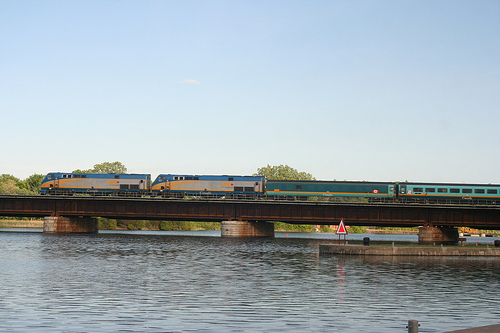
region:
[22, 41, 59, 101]
the sky is clear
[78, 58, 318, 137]
the sky is clear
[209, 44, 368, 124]
the sky is clear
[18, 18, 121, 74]
the sky is clear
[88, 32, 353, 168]
the sky is clear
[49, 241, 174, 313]
the water is calm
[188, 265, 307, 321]
the water is calm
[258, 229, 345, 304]
the water is calm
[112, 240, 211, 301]
the water is calm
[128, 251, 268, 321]
the water is calm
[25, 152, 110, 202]
blue train in the front with yellow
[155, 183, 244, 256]
second train with yellow body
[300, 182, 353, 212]
third train is green and short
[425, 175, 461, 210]
fourth train has windows on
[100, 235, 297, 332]
calm river with no ducks in it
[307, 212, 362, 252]
a random sign in middle of river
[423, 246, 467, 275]
some sort of island in middle of water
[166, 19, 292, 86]
bright blue sky with no cloud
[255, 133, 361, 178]
a random tree behind trains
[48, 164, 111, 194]
a train pilot eating a sandwich in front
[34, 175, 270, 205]
yellow and black train engines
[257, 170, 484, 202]
green train cars on bridge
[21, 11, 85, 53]
white clouds in blue sky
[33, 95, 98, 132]
white clouds in blue sky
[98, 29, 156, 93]
white clouds in blue sky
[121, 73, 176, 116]
white clouds in blue sky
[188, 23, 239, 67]
white clouds in blue sky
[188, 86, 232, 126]
white clouds in blue sky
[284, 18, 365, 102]
white clouds in blue sky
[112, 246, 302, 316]
This is a large river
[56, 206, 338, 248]
These are stumps of brick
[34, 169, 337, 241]
This is a train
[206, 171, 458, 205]
These are train cars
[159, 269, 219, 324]
The lake is brown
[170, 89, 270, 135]
There are no clouds in the sky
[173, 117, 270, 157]
There are no planes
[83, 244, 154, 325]
There are no people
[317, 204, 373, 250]
This is a triangular sign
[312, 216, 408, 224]
The sign is red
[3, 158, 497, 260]
train riding along bridge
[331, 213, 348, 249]
warning sign by water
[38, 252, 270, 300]
water by a bridge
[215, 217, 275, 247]
stone pillars of a bridge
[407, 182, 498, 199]
windows on side of train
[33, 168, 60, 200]
front of a train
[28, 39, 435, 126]
blue sky in the distance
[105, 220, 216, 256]
shadow under a bridge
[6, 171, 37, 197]
tops of green trees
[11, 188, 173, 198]
railing along side of bridge